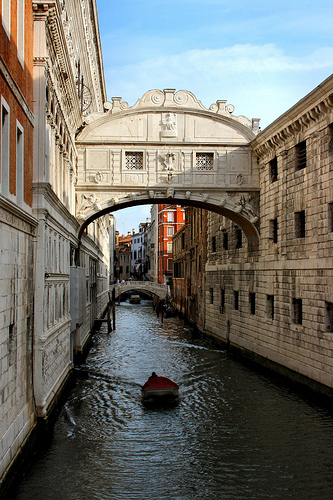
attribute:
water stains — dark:
[204, 113, 331, 369]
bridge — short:
[111, 282, 169, 304]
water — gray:
[31, 276, 331, 490]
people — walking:
[116, 277, 125, 283]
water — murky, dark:
[107, 449, 216, 493]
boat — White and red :
[136, 361, 196, 408]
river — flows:
[1, 1, 331, 497]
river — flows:
[130, 310, 184, 360]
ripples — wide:
[82, 414, 271, 497]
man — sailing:
[138, 372, 186, 410]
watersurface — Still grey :
[14, 292, 332, 499]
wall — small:
[272, 277, 297, 351]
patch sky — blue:
[106, 9, 169, 55]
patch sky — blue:
[217, 8, 319, 44]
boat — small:
[142, 374, 179, 402]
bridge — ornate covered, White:
[70, 88, 267, 240]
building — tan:
[155, 204, 186, 301]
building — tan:
[142, 203, 159, 284]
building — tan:
[129, 222, 145, 278]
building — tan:
[114, 233, 129, 280]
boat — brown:
[140, 372, 184, 402]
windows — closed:
[122, 147, 217, 172]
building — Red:
[149, 203, 181, 302]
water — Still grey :
[47, 274, 292, 496]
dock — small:
[97, 287, 122, 332]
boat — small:
[139, 369, 178, 397]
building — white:
[8, 8, 136, 441]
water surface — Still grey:
[0, 301, 332, 497]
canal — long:
[1, 278, 329, 497]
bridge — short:
[119, 267, 182, 300]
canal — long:
[107, 284, 227, 456]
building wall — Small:
[206, 88, 331, 372]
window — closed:
[258, 291, 278, 320]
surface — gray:
[176, 339, 317, 478]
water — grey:
[131, 305, 158, 334]